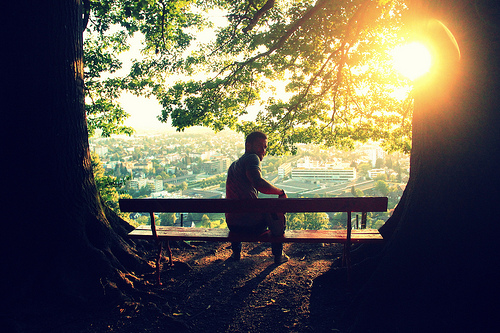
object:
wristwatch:
[278, 189, 286, 198]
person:
[222, 129, 291, 262]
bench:
[117, 195, 390, 285]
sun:
[364, 19, 463, 108]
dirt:
[162, 252, 308, 327]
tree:
[4, 0, 150, 328]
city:
[99, 139, 404, 226]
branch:
[215, 0, 327, 67]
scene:
[80, 7, 456, 286]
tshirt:
[227, 154, 261, 202]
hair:
[245, 132, 268, 141]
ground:
[162, 278, 290, 325]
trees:
[339, 0, 497, 333]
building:
[289, 168, 356, 182]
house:
[131, 158, 154, 178]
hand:
[278, 192, 289, 200]